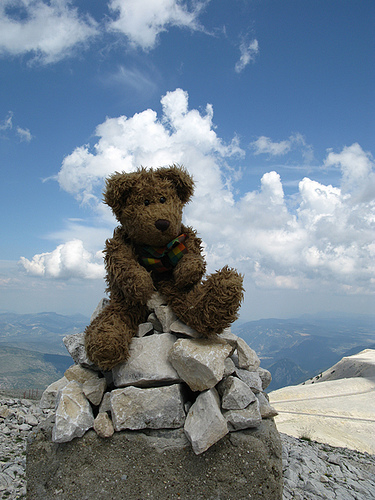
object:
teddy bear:
[83, 164, 244, 373]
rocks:
[109, 384, 185, 435]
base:
[26, 404, 282, 500]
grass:
[297, 427, 314, 437]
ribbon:
[131, 233, 189, 273]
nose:
[155, 218, 169, 235]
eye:
[142, 194, 150, 207]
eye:
[158, 194, 166, 206]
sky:
[1, 0, 374, 318]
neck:
[116, 222, 189, 246]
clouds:
[17, 239, 106, 285]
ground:
[1, 390, 374, 499]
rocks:
[181, 389, 229, 455]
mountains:
[1, 311, 374, 404]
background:
[0, 0, 374, 499]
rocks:
[49, 380, 95, 444]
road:
[2, 341, 375, 358]